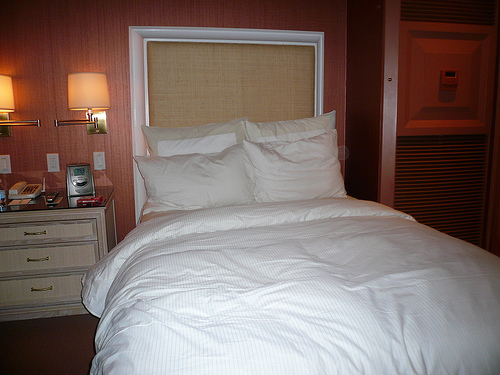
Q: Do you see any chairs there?
A: No, there are no chairs.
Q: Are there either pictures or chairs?
A: No, there are no chairs or pictures.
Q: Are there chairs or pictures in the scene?
A: No, there are no chairs or pictures.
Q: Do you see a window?
A: Yes, there is a window.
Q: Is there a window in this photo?
A: Yes, there is a window.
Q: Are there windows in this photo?
A: Yes, there is a window.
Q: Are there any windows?
A: Yes, there is a window.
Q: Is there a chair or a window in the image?
A: Yes, there is a window.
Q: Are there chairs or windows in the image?
A: Yes, there is a window.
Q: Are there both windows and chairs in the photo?
A: No, there is a window but no chairs.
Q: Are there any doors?
A: No, there are no doors.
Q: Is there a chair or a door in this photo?
A: No, there are no doors or chairs.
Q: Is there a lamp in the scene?
A: Yes, there is a lamp.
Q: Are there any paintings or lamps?
A: Yes, there is a lamp.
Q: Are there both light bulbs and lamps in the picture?
A: No, there is a lamp but no light bulbs.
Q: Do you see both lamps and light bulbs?
A: No, there is a lamp but no light bulbs.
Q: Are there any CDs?
A: No, there are no cds.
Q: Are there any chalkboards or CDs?
A: No, there are no CDs or chalkboards.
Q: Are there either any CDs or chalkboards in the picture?
A: No, there are no CDs or chalkboards.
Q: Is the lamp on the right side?
A: No, the lamp is on the left of the image.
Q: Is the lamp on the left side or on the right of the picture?
A: The lamp is on the left of the image.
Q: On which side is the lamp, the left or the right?
A: The lamp is on the left of the image.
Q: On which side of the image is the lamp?
A: The lamp is on the left of the image.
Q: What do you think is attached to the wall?
A: The lamp is attached to the wall.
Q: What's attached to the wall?
A: The lamp is attached to the wall.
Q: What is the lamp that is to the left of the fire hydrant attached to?
A: The lamp is attached to the wall.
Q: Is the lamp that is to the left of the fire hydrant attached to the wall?
A: Yes, the lamp is attached to the wall.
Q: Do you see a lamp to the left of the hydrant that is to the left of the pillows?
A: Yes, there is a lamp to the left of the fire hydrant.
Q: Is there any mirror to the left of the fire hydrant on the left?
A: No, there is a lamp to the left of the fire hydrant.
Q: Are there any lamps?
A: Yes, there is a lamp.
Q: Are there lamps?
A: Yes, there is a lamp.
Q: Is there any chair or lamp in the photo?
A: Yes, there is a lamp.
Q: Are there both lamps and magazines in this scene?
A: No, there is a lamp but no magazines.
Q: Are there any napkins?
A: No, there are no napkins.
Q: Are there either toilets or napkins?
A: No, there are no napkins or toilets.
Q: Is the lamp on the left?
A: Yes, the lamp is on the left of the image.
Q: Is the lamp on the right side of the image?
A: No, the lamp is on the left of the image.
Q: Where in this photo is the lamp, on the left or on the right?
A: The lamp is on the left of the image.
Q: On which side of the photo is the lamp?
A: The lamp is on the left of the image.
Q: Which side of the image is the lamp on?
A: The lamp is on the left of the image.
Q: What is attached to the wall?
A: The lamp is attached to the wall.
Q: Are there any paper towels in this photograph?
A: No, there are no paper towels.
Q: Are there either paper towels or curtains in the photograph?
A: No, there are no paper towels or curtains.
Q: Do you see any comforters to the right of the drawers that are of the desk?
A: Yes, there is a comforter to the right of the drawers.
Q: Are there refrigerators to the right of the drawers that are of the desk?
A: No, there is a comforter to the right of the drawers.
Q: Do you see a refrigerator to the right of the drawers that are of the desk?
A: No, there is a comforter to the right of the drawers.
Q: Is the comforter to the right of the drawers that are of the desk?
A: Yes, the comforter is to the right of the drawers.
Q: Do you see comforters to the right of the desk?
A: Yes, there is a comforter to the right of the desk.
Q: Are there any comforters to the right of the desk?
A: Yes, there is a comforter to the right of the desk.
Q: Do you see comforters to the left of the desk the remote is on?
A: No, the comforter is to the right of the desk.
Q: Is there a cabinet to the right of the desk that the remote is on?
A: No, there is a comforter to the right of the desk.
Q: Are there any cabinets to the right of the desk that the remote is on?
A: No, there is a comforter to the right of the desk.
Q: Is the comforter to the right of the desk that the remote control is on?
A: Yes, the comforter is to the right of the desk.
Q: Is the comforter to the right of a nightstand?
A: No, the comforter is to the right of the desk.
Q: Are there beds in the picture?
A: Yes, there is a bed.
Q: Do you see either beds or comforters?
A: Yes, there is a bed.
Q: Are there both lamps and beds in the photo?
A: Yes, there are both a bed and a lamp.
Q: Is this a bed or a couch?
A: This is a bed.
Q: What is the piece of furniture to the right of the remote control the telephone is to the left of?
A: The piece of furniture is a bed.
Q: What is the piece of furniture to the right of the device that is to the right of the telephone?
A: The piece of furniture is a bed.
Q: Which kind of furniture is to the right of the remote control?
A: The piece of furniture is a bed.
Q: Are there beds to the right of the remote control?
A: Yes, there is a bed to the right of the remote control.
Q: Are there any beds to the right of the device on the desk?
A: Yes, there is a bed to the right of the remote control.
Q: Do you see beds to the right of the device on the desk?
A: Yes, there is a bed to the right of the remote control.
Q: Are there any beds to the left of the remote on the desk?
A: No, the bed is to the right of the remote control.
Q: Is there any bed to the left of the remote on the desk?
A: No, the bed is to the right of the remote control.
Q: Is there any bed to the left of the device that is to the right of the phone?
A: No, the bed is to the right of the remote control.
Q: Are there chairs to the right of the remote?
A: No, there is a bed to the right of the remote.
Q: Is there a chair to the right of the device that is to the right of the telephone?
A: No, there is a bed to the right of the remote.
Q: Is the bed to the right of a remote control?
A: Yes, the bed is to the right of a remote control.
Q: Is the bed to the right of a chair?
A: No, the bed is to the right of a remote control.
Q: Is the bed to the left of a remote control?
A: No, the bed is to the right of a remote control.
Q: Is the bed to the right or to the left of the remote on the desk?
A: The bed is to the right of the remote control.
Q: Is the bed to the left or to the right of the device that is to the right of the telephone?
A: The bed is to the right of the remote control.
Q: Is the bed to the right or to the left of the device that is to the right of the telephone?
A: The bed is to the right of the remote control.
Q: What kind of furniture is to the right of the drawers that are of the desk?
A: The piece of furniture is a bed.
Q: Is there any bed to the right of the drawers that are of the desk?
A: Yes, there is a bed to the right of the drawers.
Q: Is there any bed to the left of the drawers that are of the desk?
A: No, the bed is to the right of the drawers.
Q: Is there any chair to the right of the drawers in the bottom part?
A: No, there is a bed to the right of the drawers.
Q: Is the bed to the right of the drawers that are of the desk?
A: Yes, the bed is to the right of the drawers.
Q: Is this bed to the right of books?
A: No, the bed is to the right of the drawers.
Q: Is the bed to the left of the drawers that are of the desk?
A: No, the bed is to the right of the drawers.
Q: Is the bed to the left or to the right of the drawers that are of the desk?
A: The bed is to the right of the drawers.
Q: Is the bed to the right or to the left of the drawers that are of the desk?
A: The bed is to the right of the drawers.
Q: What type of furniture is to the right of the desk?
A: The piece of furniture is a bed.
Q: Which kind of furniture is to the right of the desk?
A: The piece of furniture is a bed.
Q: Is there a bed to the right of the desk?
A: Yes, there is a bed to the right of the desk.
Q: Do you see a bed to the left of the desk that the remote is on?
A: No, the bed is to the right of the desk.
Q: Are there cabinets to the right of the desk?
A: No, there is a bed to the right of the desk.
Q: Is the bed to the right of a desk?
A: Yes, the bed is to the right of a desk.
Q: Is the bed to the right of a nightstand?
A: No, the bed is to the right of a desk.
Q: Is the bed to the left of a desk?
A: No, the bed is to the right of a desk.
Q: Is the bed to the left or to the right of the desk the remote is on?
A: The bed is to the right of the desk.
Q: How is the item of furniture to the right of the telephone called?
A: The piece of furniture is a bed.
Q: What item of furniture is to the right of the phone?
A: The piece of furniture is a bed.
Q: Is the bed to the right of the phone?
A: Yes, the bed is to the right of the phone.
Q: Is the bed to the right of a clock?
A: No, the bed is to the right of the phone.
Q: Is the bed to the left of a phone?
A: No, the bed is to the right of a phone.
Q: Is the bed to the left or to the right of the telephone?
A: The bed is to the right of the telephone.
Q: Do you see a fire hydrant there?
A: Yes, there is a fire hydrant.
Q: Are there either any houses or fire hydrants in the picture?
A: Yes, there is a fire hydrant.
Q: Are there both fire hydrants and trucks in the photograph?
A: No, there is a fire hydrant but no trucks.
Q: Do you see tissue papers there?
A: No, there are no tissue papers.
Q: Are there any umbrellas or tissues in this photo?
A: No, there are no tissues or umbrellas.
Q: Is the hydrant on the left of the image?
A: Yes, the hydrant is on the left of the image.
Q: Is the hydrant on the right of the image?
A: No, the hydrant is on the left of the image.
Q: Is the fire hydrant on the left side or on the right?
A: The fire hydrant is on the left of the image.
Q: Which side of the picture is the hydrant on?
A: The hydrant is on the left of the image.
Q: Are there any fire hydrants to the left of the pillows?
A: Yes, there is a fire hydrant to the left of the pillows.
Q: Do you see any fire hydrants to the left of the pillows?
A: Yes, there is a fire hydrant to the left of the pillows.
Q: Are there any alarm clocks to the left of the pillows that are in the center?
A: No, there is a fire hydrant to the left of the pillows.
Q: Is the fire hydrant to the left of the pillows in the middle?
A: Yes, the fire hydrant is to the left of the pillows.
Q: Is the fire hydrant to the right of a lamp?
A: Yes, the fire hydrant is to the right of a lamp.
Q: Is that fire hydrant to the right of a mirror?
A: No, the fire hydrant is to the right of a lamp.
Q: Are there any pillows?
A: Yes, there are pillows.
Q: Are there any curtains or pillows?
A: Yes, there are pillows.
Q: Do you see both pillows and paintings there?
A: No, there are pillows but no paintings.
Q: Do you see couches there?
A: No, there are no couches.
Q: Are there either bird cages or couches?
A: No, there are no couches or bird cages.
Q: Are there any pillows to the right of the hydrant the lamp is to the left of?
A: Yes, there are pillows to the right of the hydrant.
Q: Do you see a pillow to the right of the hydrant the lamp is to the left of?
A: Yes, there are pillows to the right of the hydrant.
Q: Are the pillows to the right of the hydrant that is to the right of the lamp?
A: Yes, the pillows are to the right of the hydrant.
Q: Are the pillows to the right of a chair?
A: No, the pillows are to the right of the hydrant.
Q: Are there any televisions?
A: No, there are no televisions.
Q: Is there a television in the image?
A: No, there are no televisions.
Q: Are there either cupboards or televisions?
A: No, there are no televisions or cupboards.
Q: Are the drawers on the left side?
A: Yes, the drawers are on the left of the image.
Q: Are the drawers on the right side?
A: No, the drawers are on the left of the image.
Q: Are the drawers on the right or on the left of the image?
A: The drawers are on the left of the image.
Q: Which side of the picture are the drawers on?
A: The drawers are on the left of the image.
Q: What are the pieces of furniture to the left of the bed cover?
A: The pieces of furniture are drawers.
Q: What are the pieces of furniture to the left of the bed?
A: The pieces of furniture are drawers.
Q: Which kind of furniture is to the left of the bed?
A: The pieces of furniture are drawers.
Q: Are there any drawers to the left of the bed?
A: Yes, there are drawers to the left of the bed.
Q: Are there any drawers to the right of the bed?
A: No, the drawers are to the left of the bed.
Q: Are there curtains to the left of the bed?
A: No, there are drawers to the left of the bed.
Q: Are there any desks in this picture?
A: Yes, there is a desk.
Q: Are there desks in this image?
A: Yes, there is a desk.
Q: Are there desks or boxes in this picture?
A: Yes, there is a desk.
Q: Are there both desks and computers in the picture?
A: No, there is a desk but no computers.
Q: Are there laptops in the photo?
A: No, there are no laptops.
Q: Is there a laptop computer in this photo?
A: No, there are no laptops.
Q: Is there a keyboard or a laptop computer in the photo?
A: No, there are no laptops or keyboards.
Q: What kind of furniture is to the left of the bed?
A: The piece of furniture is a desk.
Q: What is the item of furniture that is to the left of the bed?
A: The piece of furniture is a desk.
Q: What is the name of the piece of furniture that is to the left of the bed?
A: The piece of furniture is a desk.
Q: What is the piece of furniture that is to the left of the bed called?
A: The piece of furniture is a desk.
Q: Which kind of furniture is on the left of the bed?
A: The piece of furniture is a desk.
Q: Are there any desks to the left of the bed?
A: Yes, there is a desk to the left of the bed.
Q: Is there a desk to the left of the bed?
A: Yes, there is a desk to the left of the bed.